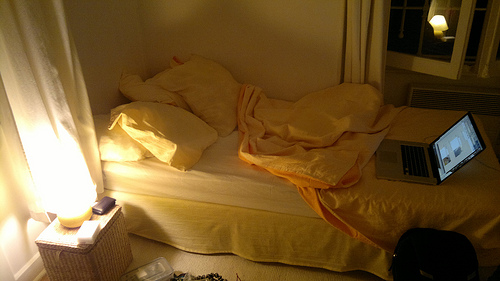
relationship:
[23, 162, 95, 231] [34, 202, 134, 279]
lamp on night stand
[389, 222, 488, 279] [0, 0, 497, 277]
object in room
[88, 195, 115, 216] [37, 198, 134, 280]
object on nightstand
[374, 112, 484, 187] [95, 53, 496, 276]
lap top on bed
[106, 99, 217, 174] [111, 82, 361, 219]
pillow on bed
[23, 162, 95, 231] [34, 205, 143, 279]
lamp on nightstand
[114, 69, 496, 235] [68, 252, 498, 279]
bed on floor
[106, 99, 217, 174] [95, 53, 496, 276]
pillow on bed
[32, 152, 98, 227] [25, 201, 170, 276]
lamp on top of nightstand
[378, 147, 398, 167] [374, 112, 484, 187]
track pad on lap top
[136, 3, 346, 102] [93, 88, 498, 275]
wall by bed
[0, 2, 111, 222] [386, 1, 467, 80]
curtain on window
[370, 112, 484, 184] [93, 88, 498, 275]
lap top on bed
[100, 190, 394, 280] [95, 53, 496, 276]
skirt on bed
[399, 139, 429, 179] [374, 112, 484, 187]
keys on lap top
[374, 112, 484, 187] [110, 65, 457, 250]
lap top on bed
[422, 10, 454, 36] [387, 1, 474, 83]
reflection in window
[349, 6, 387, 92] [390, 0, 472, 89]
curtain by window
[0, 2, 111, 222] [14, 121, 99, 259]
curtain hanging by lamp